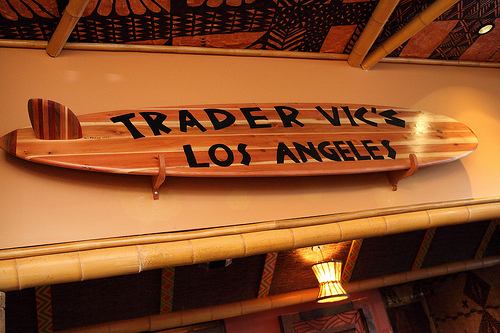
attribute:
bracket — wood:
[384, 153, 418, 189]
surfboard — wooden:
[11, 92, 480, 179]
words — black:
[183, 139, 397, 167]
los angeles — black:
[183, 140, 395, 167]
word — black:
[196, 109, 239, 204]